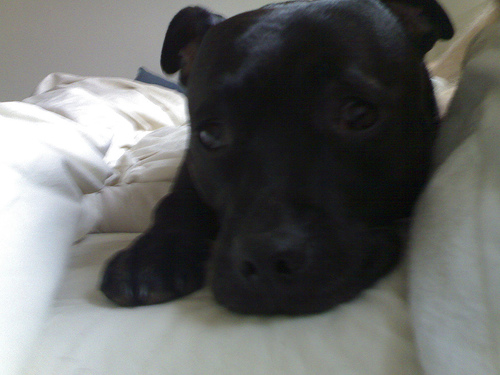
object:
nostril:
[241, 260, 257, 279]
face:
[186, 0, 442, 316]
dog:
[99, 0, 455, 316]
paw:
[98, 250, 203, 308]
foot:
[98, 149, 219, 308]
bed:
[0, 0, 499, 374]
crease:
[73, 117, 190, 243]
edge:
[0, 63, 178, 106]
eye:
[199, 122, 235, 149]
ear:
[160, 5, 228, 86]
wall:
[0, 0, 288, 103]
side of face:
[366, 61, 440, 289]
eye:
[339, 97, 378, 131]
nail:
[137, 283, 151, 301]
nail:
[121, 286, 134, 300]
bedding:
[0, 0, 500, 373]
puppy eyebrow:
[328, 63, 389, 103]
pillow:
[133, 67, 184, 94]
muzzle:
[209, 205, 377, 316]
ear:
[379, 0, 455, 43]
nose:
[230, 230, 308, 287]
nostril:
[275, 259, 290, 274]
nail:
[173, 277, 186, 292]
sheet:
[0, 99, 419, 375]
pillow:
[404, 1, 500, 375]